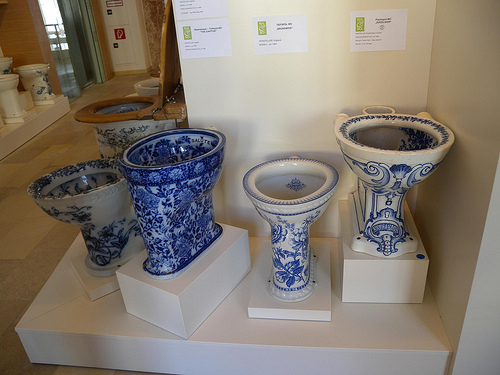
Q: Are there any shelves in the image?
A: No, there are no shelves.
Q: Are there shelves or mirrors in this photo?
A: No, there are no shelves or mirrors.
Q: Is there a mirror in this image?
A: No, there are no mirrors.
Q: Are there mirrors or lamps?
A: No, there are no mirrors or lamps.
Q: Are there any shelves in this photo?
A: No, there are no shelves.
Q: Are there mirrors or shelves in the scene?
A: No, there are no shelves or mirrors.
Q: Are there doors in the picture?
A: Yes, there are doors.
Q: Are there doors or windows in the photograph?
A: Yes, there are doors.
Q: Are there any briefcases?
A: No, there are no briefcases.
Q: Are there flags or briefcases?
A: No, there are no briefcases or flags.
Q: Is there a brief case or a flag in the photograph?
A: No, there are no briefcases or flags.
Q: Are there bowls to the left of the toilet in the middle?
A: Yes, there is a bowl to the left of the toilet.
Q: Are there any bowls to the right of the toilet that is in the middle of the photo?
A: No, the bowl is to the left of the toilet.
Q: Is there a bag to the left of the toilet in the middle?
A: No, there is a bowl to the left of the toilet.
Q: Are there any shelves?
A: No, there are no shelves.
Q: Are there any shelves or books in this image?
A: No, there are no shelves or books.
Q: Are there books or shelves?
A: No, there are no shelves or books.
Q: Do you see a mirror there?
A: No, there are no mirrors.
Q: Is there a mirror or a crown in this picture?
A: No, there are no mirrors or crowns.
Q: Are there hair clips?
A: No, there are no hair clips.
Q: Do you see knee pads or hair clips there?
A: No, there are no hair clips or knee pads.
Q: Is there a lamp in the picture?
A: No, there are no lamps.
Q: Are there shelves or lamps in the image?
A: No, there are no lamps or shelves.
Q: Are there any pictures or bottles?
A: No, there are no pictures or bottles.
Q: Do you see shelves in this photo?
A: No, there are no shelves.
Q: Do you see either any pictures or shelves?
A: No, there are no shelves or pictures.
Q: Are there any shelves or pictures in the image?
A: No, there are no shelves or pictures.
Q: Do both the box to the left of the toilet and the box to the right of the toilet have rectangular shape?
A: Yes, both the box and the box are rectangular.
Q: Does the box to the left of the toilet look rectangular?
A: Yes, the box is rectangular.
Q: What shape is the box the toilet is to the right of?
A: The box is rectangular.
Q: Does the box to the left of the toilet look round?
A: No, the box is rectangular.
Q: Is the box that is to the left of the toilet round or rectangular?
A: The box is rectangular.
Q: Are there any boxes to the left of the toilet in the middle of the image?
A: Yes, there is a box to the left of the toilet.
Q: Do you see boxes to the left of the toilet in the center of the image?
A: Yes, there is a box to the left of the toilet.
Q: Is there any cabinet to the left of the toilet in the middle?
A: No, there is a box to the left of the toilet.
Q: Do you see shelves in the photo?
A: No, there are no shelves.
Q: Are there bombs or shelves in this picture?
A: No, there are no shelves or bombs.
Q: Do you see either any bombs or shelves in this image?
A: No, there are no shelves or bombs.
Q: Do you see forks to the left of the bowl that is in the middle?
A: No, there is a toilet to the left of the bowl.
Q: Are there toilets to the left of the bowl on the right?
A: Yes, there is a toilet to the left of the bowl.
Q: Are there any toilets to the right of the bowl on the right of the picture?
A: No, the toilet is to the left of the bowl.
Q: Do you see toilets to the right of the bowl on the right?
A: No, the toilet is to the left of the bowl.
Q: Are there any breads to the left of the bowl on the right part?
A: No, there is a toilet to the left of the bowl.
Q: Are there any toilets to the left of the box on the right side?
A: Yes, there is a toilet to the left of the box.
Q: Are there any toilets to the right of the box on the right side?
A: No, the toilet is to the left of the box.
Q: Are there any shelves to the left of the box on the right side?
A: No, there is a toilet to the left of the box.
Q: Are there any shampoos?
A: No, there are no shampoos.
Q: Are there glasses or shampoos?
A: No, there are no shampoos or glasses.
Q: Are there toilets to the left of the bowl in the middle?
A: Yes, there is a toilet to the left of the bowl.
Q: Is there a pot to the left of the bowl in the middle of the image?
A: No, there is a toilet to the left of the bowl.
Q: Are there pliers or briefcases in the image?
A: No, there are no briefcases or pliers.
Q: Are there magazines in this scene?
A: No, there are no magazines.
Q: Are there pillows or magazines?
A: No, there are no magazines or pillows.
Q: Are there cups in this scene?
A: Yes, there is a cup.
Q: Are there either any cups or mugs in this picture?
A: Yes, there is a cup.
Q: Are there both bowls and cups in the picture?
A: Yes, there are both a cup and a bowl.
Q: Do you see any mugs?
A: No, there are no mugs.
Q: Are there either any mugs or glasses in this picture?
A: No, there are no mugs or glasses.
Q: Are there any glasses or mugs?
A: No, there are no mugs or glasses.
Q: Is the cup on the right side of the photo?
A: Yes, the cup is on the right of the image.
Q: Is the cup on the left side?
A: No, the cup is on the right of the image.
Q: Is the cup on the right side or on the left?
A: The cup is on the right of the image.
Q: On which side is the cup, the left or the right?
A: The cup is on the right of the image.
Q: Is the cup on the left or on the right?
A: The cup is on the right of the image.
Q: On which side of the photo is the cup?
A: The cup is on the right of the image.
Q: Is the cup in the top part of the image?
A: Yes, the cup is in the top of the image.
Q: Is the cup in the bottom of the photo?
A: No, the cup is in the top of the image.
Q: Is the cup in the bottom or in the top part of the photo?
A: The cup is in the top of the image.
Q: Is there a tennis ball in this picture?
A: No, there are no tennis balls.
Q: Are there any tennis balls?
A: No, there are no tennis balls.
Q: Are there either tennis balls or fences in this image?
A: No, there are no tennis balls or fences.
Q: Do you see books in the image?
A: No, there are no books.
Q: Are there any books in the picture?
A: No, there are no books.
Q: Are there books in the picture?
A: No, there are no books.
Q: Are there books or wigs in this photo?
A: No, there are no books or wigs.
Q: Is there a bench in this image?
A: No, there are no benches.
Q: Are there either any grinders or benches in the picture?
A: No, there are no benches or grinders.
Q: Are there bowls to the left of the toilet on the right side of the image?
A: Yes, there is a bowl to the left of the toilet.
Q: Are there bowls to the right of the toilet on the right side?
A: No, the bowl is to the left of the toilet.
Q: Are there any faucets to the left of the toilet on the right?
A: No, there is a bowl to the left of the toilet.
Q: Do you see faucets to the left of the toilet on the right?
A: No, there is a bowl to the left of the toilet.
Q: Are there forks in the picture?
A: No, there are no forks.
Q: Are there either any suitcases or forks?
A: No, there are no forks or suitcases.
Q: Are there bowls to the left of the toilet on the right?
A: Yes, there is a bowl to the left of the toilet.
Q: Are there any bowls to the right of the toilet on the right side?
A: No, the bowl is to the left of the toilet.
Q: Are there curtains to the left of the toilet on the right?
A: No, there is a bowl to the left of the toilet.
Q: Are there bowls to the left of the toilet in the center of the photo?
A: Yes, there is a bowl to the left of the toilet.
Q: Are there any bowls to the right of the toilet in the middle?
A: No, the bowl is to the left of the toilet.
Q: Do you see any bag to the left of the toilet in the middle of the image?
A: No, there is a bowl to the left of the toilet.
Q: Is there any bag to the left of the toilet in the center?
A: No, there is a bowl to the left of the toilet.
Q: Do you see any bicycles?
A: No, there are no bicycles.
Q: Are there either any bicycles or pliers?
A: No, there are no bicycles or pliers.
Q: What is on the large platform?
A: The bowl is on the platform.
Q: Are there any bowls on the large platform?
A: Yes, there is a bowl on the platform.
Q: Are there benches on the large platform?
A: No, there is a bowl on the platform.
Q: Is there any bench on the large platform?
A: No, there is a bowl on the platform.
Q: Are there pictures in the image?
A: No, there are no pictures.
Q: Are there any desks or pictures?
A: No, there are no pictures or desks.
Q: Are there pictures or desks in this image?
A: No, there are no pictures or desks.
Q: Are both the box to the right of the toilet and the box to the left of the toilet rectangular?
A: Yes, both the box and the box are rectangular.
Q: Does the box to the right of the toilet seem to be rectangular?
A: Yes, the box is rectangular.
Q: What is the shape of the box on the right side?
A: The box is rectangular.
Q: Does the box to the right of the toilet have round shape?
A: No, the box is rectangular.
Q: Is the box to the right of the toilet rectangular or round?
A: The box is rectangular.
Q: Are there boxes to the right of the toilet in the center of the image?
A: Yes, there is a box to the right of the toilet.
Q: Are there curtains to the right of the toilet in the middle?
A: No, there is a box to the right of the toilet.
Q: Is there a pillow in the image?
A: No, there are no pillows.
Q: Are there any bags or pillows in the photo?
A: No, there are no pillows or bags.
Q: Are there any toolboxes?
A: No, there are no toolboxes.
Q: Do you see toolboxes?
A: No, there are no toolboxes.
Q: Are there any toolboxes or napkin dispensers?
A: No, there are no toolboxes or napkin dispensers.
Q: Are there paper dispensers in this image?
A: No, there are no paper dispensers.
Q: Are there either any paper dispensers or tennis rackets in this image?
A: No, there are no paper dispensers or tennis rackets.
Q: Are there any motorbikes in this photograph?
A: No, there are no motorbikes.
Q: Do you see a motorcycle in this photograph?
A: No, there are no motorcycles.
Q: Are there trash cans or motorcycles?
A: No, there are no motorcycles or trash cans.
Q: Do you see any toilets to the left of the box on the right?
A: Yes, there is a toilet to the left of the box.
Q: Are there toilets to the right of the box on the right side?
A: No, the toilet is to the left of the box.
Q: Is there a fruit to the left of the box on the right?
A: No, there is a toilet to the left of the box.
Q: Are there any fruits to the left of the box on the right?
A: No, there is a toilet to the left of the box.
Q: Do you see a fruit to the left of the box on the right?
A: No, there is a toilet to the left of the box.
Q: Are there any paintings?
A: No, there are no paintings.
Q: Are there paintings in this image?
A: No, there are no paintings.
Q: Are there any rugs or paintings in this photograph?
A: No, there are no paintings or rugs.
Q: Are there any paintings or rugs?
A: No, there are no paintings or rugs.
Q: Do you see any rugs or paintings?
A: No, there are no paintings or rugs.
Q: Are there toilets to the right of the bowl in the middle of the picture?
A: Yes, there is a toilet to the right of the bowl.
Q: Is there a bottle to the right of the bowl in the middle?
A: No, there is a toilet to the right of the bowl.